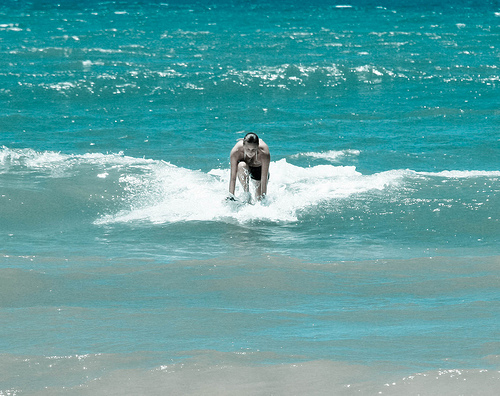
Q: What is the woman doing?
A: Surfing.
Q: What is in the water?
A: Waves.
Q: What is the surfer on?
A: Disturbed white water.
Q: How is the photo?
A: Clear.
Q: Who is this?
A: A boy with dark hair in the ocean.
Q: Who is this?
A: A boy on a surfboard in the ocean.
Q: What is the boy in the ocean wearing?
A: Black shorts.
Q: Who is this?
A: A lady kneeling in water.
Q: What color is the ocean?
A: Blue.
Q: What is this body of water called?
A: The ocean.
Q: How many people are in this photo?
A: One.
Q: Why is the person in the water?
A: To surf.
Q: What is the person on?
A: A surfboard.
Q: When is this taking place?
A: Daytime.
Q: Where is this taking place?
A: The ocean.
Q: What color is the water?
A: Blue.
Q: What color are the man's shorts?
A: Black.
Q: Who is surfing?
A: A man.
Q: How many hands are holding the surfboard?
A: Two.